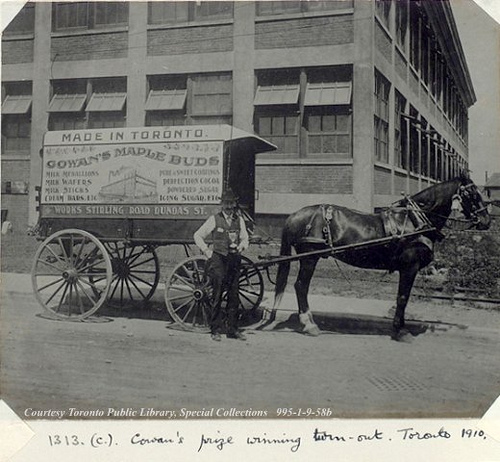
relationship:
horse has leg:
[273, 171, 490, 344] [389, 265, 418, 344]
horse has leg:
[273, 171, 490, 344] [291, 244, 321, 334]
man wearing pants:
[190, 189, 252, 339] [206, 249, 243, 338]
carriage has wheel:
[27, 122, 276, 332] [29, 225, 115, 322]